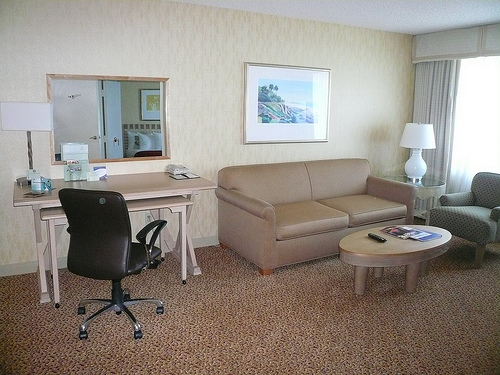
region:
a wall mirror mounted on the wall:
[43, 71, 170, 160]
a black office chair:
[58, 187, 164, 339]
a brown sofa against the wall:
[214, 155, 414, 220]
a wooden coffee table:
[337, 225, 452, 297]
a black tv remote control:
[365, 230, 387, 245]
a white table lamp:
[399, 121, 435, 183]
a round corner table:
[394, 175, 446, 222]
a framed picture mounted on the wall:
[242, 60, 332, 147]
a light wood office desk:
[164, 168, 216, 283]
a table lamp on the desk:
[1, 98, 52, 185]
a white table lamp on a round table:
[382, 122, 444, 220]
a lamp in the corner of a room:
[361, 18, 466, 229]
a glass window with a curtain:
[414, 30, 496, 235]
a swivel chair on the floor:
[59, 185, 174, 374]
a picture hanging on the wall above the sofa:
[216, 58, 414, 271]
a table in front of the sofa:
[217, 154, 452, 299]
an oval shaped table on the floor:
[336, 218, 454, 311]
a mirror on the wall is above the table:
[4, 69, 215, 301]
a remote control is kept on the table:
[338, 221, 452, 296]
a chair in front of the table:
[11, 167, 220, 340]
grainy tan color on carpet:
[213, 318, 349, 356]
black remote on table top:
[362, 227, 395, 251]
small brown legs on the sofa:
[249, 263, 287, 279]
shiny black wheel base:
[65, 270, 173, 353]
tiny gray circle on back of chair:
[96, 195, 112, 207]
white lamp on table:
[386, 114, 449, 183]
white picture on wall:
[234, 54, 350, 152]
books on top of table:
[375, 218, 446, 245]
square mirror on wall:
[38, 63, 182, 163]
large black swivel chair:
[45, 178, 183, 350]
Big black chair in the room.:
[65, 179, 165, 294]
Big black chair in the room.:
[9, 39, 40, 80]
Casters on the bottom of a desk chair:
[73, 293, 168, 343]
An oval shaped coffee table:
[335, 220, 450, 296]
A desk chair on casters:
[55, 185, 171, 346]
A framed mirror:
[44, 70, 177, 166]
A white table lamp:
[398, 118, 435, 181]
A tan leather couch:
[216, 157, 421, 270]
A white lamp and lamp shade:
[398, 120, 441, 182]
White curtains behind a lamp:
[411, 60, 461, 194]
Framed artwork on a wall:
[240, 58, 333, 148]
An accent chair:
[428, 170, 498, 266]